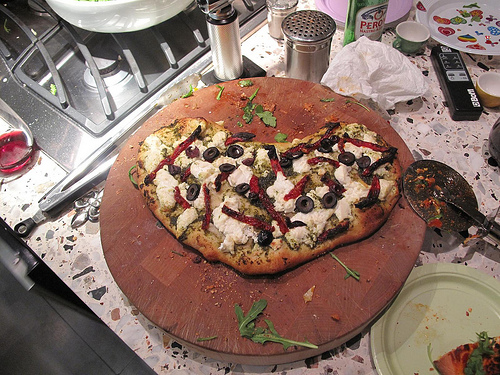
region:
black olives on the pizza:
[292, 191, 341, 213]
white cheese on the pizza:
[210, 207, 255, 246]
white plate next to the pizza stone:
[365, 260, 498, 374]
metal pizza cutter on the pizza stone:
[398, 157, 497, 250]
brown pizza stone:
[95, 76, 430, 364]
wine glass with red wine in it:
[0, 89, 40, 186]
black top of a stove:
[1, 0, 296, 170]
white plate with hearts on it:
[410, 1, 499, 61]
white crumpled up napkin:
[317, 33, 432, 111]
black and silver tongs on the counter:
[6, 69, 203, 242]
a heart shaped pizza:
[89, 27, 441, 372]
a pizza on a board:
[74, 30, 475, 366]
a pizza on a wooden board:
[143, 67, 460, 370]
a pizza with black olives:
[111, 30, 439, 296]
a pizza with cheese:
[110, 12, 488, 342]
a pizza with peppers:
[122, 48, 442, 340]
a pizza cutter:
[317, 127, 494, 293]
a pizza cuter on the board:
[171, 62, 490, 228]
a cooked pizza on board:
[107, 57, 365, 357]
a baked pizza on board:
[148, 53, 483, 373]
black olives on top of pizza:
[248, 227, 285, 247]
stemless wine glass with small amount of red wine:
[0, 123, 39, 168]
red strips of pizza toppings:
[193, 188, 224, 231]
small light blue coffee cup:
[384, 18, 443, 49]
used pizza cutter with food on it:
[399, 155, 497, 250]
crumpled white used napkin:
[343, 43, 430, 111]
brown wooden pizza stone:
[152, 242, 250, 346]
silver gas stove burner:
[55, 30, 153, 95]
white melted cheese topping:
[214, 206, 252, 249]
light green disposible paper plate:
[427, 266, 498, 363]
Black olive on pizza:
[203, 146, 223, 165]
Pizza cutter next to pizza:
[403, 155, 498, 255]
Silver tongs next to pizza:
[6, 67, 209, 241]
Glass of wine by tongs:
[0, 90, 35, 177]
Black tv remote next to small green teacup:
[432, 40, 481, 121]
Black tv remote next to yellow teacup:
[429, 45, 484, 117]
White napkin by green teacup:
[318, 32, 428, 110]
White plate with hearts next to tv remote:
[412, 0, 497, 55]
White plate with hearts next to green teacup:
[412, 0, 499, 58]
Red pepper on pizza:
[241, 169, 288, 234]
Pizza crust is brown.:
[152, 105, 417, 280]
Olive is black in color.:
[205, 140, 220, 162]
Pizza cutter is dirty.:
[407, 141, 478, 241]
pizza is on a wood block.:
[130, 65, 395, 365]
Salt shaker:
[205, 15, 245, 75]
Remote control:
[427, 41, 497, 92]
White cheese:
[215, 205, 250, 245]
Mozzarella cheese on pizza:
[217, 210, 252, 236]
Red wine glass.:
[0, 126, 27, 171]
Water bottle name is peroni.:
[350, 3, 390, 34]